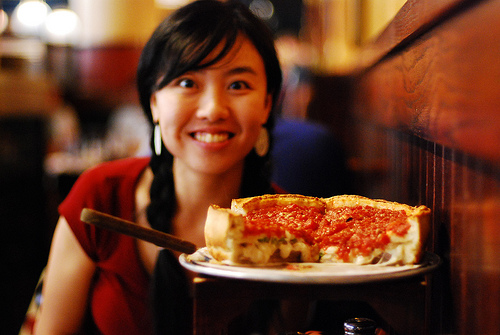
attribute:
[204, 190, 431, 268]
pizza — large, thick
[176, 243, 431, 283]
plate — white, ceramic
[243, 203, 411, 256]
sauce — red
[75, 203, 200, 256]
handle — wooden, brown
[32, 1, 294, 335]
woman — smiling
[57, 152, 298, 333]
shirt — red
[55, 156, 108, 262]
sleeve — short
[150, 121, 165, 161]
earring — round, large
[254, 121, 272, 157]
earring — round, large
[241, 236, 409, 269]
cheese — melted, white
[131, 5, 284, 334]
hair — long, black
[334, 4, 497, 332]
wall — wooden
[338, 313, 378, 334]
shaker — silver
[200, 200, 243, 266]
crust — baked